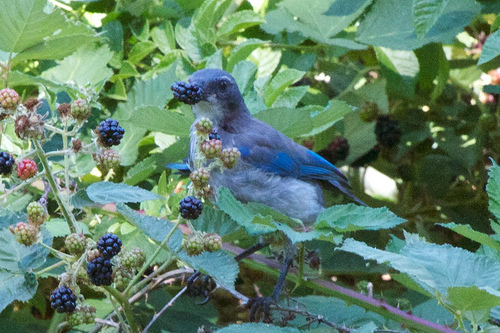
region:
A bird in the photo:
[173, 65, 365, 271]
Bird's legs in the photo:
[198, 226, 308, 301]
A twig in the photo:
[325, 281, 435, 331]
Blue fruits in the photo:
[87, 231, 133, 292]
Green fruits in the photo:
[59, 230, 87, 259]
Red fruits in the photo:
[12, 149, 49, 194]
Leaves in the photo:
[62, 19, 157, 109]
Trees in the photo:
[375, 52, 462, 243]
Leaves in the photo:
[312, 34, 464, 152]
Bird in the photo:
[182, 71, 357, 271]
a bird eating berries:
[153, 67, 353, 323]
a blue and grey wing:
[216, 105, 356, 192]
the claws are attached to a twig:
[169, 234, 321, 329]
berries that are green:
[10, 192, 90, 271]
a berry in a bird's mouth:
[153, 57, 269, 119]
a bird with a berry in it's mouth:
[141, 52, 261, 120]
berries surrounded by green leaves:
[281, 11, 493, 192]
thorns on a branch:
[230, 238, 450, 330]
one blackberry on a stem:
[156, 114, 272, 262]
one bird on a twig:
[142, 63, 339, 321]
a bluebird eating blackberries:
[149, 60, 382, 330]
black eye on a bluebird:
[216, 77, 232, 92]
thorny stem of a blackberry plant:
[283, 270, 453, 331]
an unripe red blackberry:
[13, 155, 38, 181]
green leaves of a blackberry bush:
[6, 3, 497, 330]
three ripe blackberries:
[46, 230, 126, 320]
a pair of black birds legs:
[182, 233, 302, 326]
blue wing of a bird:
[228, 116, 353, 190]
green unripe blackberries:
[11, 195, 50, 249]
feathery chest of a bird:
[218, 160, 288, 210]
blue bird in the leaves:
[165, 68, 363, 323]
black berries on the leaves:
[75, 233, 122, 285]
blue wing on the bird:
[284, 140, 348, 180]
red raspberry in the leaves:
[13, 150, 37, 180]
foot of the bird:
[250, 289, 289, 326]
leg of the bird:
[272, 259, 292, 289]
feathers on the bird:
[245, 172, 294, 202]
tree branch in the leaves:
[317, 273, 382, 310]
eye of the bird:
[210, 77, 234, 94]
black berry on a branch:
[367, 108, 409, 155]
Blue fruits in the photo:
[171, 189, 237, 234]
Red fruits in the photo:
[6, 159, 46, 182]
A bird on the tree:
[172, 59, 361, 243]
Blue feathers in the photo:
[237, 151, 331, 181]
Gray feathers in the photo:
[234, 119, 276, 154]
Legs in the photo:
[242, 241, 294, 301]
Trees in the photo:
[332, 187, 469, 322]